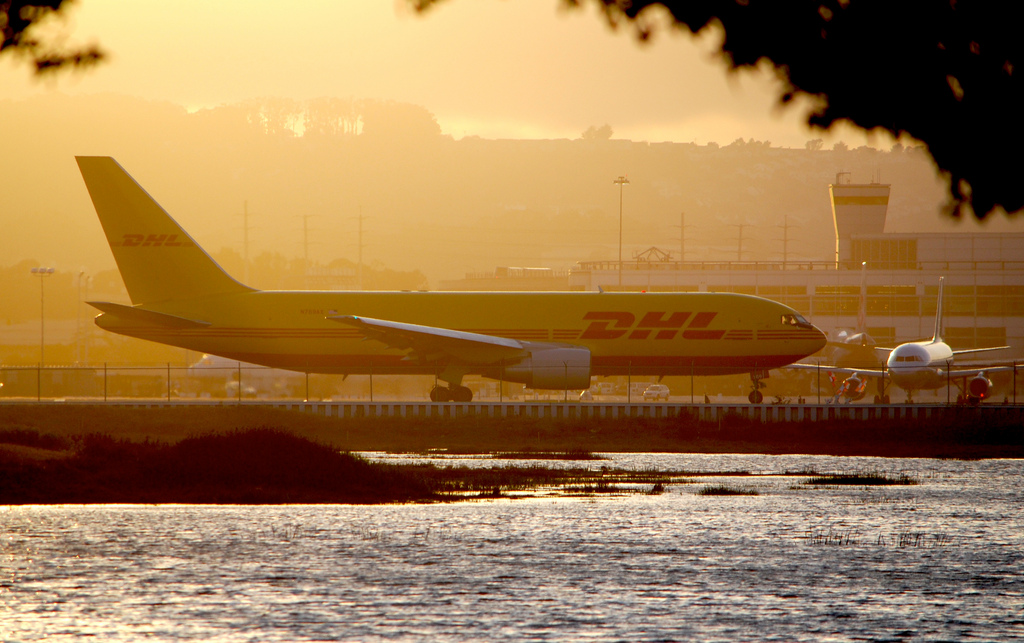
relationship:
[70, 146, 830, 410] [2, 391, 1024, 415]
plane on runway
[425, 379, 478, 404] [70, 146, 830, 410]
wheels on plane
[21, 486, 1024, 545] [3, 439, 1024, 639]
sunlight on water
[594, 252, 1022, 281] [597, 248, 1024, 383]
top fo building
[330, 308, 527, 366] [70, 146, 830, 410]
wing of plane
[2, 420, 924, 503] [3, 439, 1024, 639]
grass along water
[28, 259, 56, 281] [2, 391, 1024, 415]
lights of runway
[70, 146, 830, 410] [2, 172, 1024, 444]
plane at airport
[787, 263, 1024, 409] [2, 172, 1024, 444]
plane at airport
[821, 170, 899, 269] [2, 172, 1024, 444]
tower at airport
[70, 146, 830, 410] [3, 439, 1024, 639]
plane by water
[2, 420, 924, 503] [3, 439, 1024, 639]
grass by water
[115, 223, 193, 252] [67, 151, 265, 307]
logo on tail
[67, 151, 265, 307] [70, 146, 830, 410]
tail of plane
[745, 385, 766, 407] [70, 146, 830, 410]
wheels on plane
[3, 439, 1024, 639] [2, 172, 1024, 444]
water near airport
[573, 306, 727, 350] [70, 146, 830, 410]
sign on plane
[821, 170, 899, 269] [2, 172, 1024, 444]
tower of airport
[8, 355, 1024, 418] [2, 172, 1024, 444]
fence surrounding airport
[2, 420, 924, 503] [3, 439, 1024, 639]
grass in water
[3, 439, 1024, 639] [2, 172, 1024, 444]
water outside airport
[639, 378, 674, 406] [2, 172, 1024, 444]
car at airport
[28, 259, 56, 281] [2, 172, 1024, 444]
lights in airport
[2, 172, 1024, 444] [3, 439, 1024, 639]
airport with water